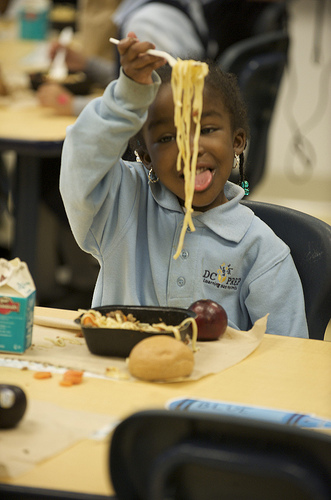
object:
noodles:
[173, 72, 203, 261]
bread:
[127, 336, 194, 383]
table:
[0, 303, 331, 498]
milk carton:
[0, 255, 37, 354]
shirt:
[58, 60, 308, 337]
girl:
[58, 33, 309, 342]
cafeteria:
[0, 3, 328, 500]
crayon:
[164, 398, 331, 431]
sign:
[167, 400, 331, 430]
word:
[195, 401, 245, 414]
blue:
[204, 403, 239, 415]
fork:
[109, 36, 209, 79]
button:
[176, 275, 186, 287]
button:
[180, 249, 189, 260]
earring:
[148, 166, 159, 184]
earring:
[232, 152, 239, 170]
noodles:
[173, 64, 182, 154]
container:
[73, 304, 198, 359]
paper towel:
[0, 306, 270, 385]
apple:
[188, 299, 228, 342]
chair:
[239, 198, 331, 343]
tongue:
[195, 170, 212, 193]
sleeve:
[58, 66, 162, 259]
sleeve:
[245, 248, 309, 340]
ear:
[138, 145, 153, 170]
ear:
[233, 128, 246, 155]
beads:
[242, 181, 245, 189]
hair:
[154, 59, 250, 190]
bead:
[244, 188, 249, 196]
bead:
[244, 180, 248, 188]